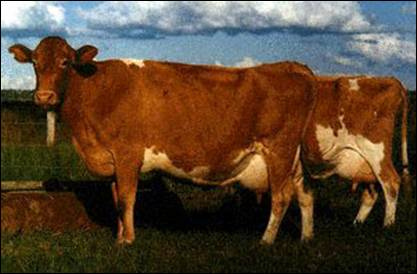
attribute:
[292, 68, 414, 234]
cow — brown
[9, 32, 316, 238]
cow — brown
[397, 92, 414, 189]
cow tail — brown, white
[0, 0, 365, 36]
clouds — white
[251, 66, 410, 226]
cows — brown, white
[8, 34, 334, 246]
cows — white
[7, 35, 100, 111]
face — brown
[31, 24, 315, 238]
cow — brown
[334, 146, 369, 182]
udder — engorged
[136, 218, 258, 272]
grass — underneath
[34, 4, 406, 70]
sky — blue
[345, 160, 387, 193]
utters — pink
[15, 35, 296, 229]
cow — brown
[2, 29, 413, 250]
cows — standing up, white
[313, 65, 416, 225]
cow — brown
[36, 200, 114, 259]
grass — short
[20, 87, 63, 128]
nose — pink